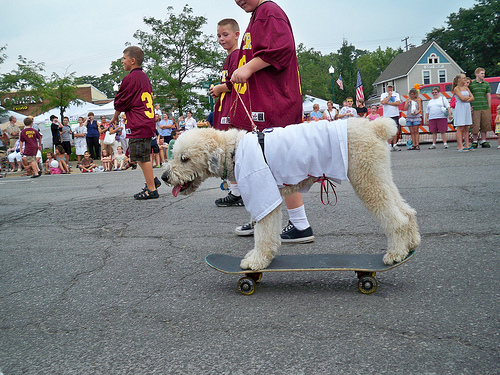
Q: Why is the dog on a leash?
A: They're in public.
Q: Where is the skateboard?
A: Under the dog.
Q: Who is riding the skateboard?
A: The dog.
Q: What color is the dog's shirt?
A: White.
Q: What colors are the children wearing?
A: Maroon and Yellow.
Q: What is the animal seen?
A: A dog.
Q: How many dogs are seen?
A: One.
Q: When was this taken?
A: During the day.